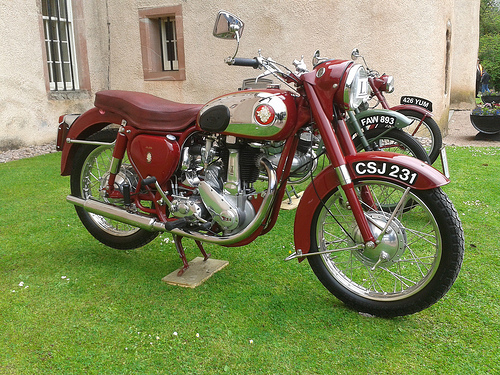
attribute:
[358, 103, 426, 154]
faw893 — white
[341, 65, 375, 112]
headlight — round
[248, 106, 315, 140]
circle — red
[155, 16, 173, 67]
bars — black, iron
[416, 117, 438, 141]
ground — red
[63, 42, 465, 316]
bike — red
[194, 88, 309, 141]
gas tank — silver, red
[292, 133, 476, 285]
fender — red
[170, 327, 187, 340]
flower — small, white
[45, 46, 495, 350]
motorcycle — red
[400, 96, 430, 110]
426yum — white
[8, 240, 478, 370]
lawn — green, grass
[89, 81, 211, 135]
seat — leather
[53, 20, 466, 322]
motorcycle — red